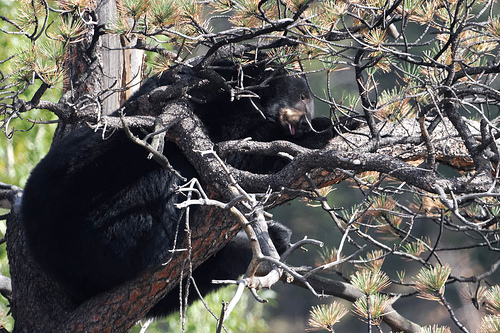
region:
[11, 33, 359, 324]
A black bear sleeping on a tree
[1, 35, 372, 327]
A grizzly bear by felled trees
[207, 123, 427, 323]
branches on the tree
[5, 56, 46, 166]
leaves on the branches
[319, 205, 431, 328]
sprigs on the branches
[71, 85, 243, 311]
the bear is black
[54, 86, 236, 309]
the bear is furry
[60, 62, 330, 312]
the bear is in tree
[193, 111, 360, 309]
the bark on branches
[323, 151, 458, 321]
the sprigs are green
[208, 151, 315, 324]
some branches are bare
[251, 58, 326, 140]
nose is on bear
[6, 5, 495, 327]
black bear curled up on tree branch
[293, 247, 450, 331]
fan-like growth on tips of branches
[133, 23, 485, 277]
branches and twigs curving and twisting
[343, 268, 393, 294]
green and tan needles flaring out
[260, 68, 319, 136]
round head with beady eye and tan snout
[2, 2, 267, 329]
green growth behind bear and tree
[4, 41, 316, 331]
bear wedged into joint of split branch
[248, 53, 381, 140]
head laying on outstretched front leg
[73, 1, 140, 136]
straight gray pole behind branches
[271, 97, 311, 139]
red tongue hanging down below snout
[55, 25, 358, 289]
a animal in the tree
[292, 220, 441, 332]
green flowers in the tree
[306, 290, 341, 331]
a flower flushing out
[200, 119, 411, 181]
a part of the stem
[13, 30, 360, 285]
a animal sitting in the tree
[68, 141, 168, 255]
skin of the animal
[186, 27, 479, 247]
face of the cow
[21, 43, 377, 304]
black cow sitting in top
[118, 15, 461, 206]
a tree with dried leaves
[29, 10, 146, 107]
a big stem of tree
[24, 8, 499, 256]
LARGE TREE BRANCH WITH LEAVES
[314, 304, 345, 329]
SMALL BUNCH OF LEAVES ON TREE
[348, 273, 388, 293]
SMALL BUNCH OF LEAVES ON TREE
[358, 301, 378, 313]
SMALL BUNCH OF LEAVES ON TREE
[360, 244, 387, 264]
SMALL BUNCH OF LEAVES ON TREE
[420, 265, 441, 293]
SMALL BUNCH OF LEAVES ON TREE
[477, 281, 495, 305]
SMALL BUNCH OF LEAVES ON TREE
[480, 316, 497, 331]
SMALL BUNCH OF LEAVES ON TREE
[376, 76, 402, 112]
SMALL BUNCH OF LEAVES ON TREE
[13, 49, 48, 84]
SMALL BUNCH OF LEAVES ON TREE